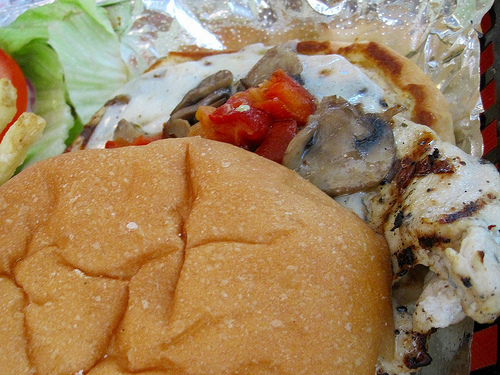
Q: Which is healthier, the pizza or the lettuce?
A: The lettuce is healthier than the pizza.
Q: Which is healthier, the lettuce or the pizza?
A: The lettuce is healthier than the pizza.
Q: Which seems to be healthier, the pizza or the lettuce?
A: The lettuce is healthier than the pizza.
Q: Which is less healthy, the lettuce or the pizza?
A: The pizza is less healthy than the lettuce.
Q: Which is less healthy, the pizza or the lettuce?
A: The pizza is less healthy than the lettuce.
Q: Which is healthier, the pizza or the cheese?
A: The cheese is healthier than the pizza.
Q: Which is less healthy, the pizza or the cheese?
A: The pizza is less healthy than the cheese.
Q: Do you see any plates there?
A: Yes, there is a plate.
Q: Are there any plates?
A: Yes, there is a plate.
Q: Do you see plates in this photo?
A: Yes, there is a plate.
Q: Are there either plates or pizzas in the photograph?
A: Yes, there is a plate.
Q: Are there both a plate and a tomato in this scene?
A: Yes, there are both a plate and a tomato.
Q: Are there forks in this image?
A: No, there are no forks.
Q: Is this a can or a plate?
A: This is a plate.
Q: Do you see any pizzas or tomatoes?
A: Yes, there is a tomato.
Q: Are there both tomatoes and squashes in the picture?
A: No, there is a tomato but no squashes.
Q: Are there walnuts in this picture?
A: No, there are no walnuts.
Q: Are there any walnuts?
A: No, there are no walnuts.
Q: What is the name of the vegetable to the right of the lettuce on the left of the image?
A: The vegetable is a tomato.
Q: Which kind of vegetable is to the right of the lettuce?
A: The vegetable is a tomato.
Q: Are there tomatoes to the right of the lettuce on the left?
A: Yes, there is a tomato to the right of the lettuce.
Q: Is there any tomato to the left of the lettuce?
A: No, the tomato is to the right of the lettuce.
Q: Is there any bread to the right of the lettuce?
A: No, there is a tomato to the right of the lettuce.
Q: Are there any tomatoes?
A: Yes, there is a tomato.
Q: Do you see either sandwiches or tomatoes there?
A: Yes, there is a tomato.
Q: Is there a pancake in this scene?
A: No, there are no pancakes.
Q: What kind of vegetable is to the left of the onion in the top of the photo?
A: The vegetable is a tomato.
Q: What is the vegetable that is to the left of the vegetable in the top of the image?
A: The vegetable is a tomato.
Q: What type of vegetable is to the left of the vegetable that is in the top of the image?
A: The vegetable is a tomato.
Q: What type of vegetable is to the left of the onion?
A: The vegetable is a tomato.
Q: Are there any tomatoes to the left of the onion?
A: Yes, there is a tomato to the left of the onion.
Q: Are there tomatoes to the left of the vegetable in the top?
A: Yes, there is a tomato to the left of the onion.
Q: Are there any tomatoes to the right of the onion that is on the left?
A: No, the tomato is to the left of the onion.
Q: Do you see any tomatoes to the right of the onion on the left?
A: No, the tomato is to the left of the onion.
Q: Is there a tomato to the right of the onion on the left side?
A: No, the tomato is to the left of the onion.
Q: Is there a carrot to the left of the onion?
A: No, there is a tomato to the left of the onion.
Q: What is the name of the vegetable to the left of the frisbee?
A: The vegetable is a tomato.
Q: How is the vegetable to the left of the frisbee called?
A: The vegetable is a tomato.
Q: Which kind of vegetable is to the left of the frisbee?
A: The vegetable is a tomato.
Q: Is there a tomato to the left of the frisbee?
A: Yes, there is a tomato to the left of the frisbee.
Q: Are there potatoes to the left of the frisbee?
A: No, there is a tomato to the left of the frisbee.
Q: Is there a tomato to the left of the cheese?
A: Yes, there is a tomato to the left of the cheese.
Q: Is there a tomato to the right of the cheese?
A: No, the tomato is to the left of the cheese.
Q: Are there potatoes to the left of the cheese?
A: No, there is a tomato to the left of the cheese.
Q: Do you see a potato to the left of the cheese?
A: No, there is a tomato to the left of the cheese.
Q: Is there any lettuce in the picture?
A: Yes, there is lettuce.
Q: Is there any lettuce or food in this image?
A: Yes, there is lettuce.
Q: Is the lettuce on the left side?
A: Yes, the lettuce is on the left of the image.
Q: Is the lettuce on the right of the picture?
A: No, the lettuce is on the left of the image.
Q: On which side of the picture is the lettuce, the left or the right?
A: The lettuce is on the left of the image.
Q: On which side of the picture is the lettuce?
A: The lettuce is on the left of the image.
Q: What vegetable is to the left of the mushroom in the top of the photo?
A: The vegetable is lettuce.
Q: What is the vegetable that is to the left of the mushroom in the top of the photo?
A: The vegetable is lettuce.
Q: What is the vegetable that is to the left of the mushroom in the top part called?
A: The vegetable is lettuce.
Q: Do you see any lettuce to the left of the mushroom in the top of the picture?
A: Yes, there is lettuce to the left of the mushroom.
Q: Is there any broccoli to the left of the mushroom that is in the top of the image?
A: No, there is lettuce to the left of the mushroom.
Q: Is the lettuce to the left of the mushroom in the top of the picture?
A: Yes, the lettuce is to the left of the mushroom.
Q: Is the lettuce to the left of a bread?
A: No, the lettuce is to the left of the mushroom.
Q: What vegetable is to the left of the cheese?
A: The vegetable is lettuce.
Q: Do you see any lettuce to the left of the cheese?
A: Yes, there is lettuce to the left of the cheese.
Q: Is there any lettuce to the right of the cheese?
A: No, the lettuce is to the left of the cheese.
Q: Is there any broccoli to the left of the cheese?
A: No, there is lettuce to the left of the cheese.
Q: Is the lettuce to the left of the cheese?
A: Yes, the lettuce is to the left of the cheese.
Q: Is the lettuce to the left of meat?
A: No, the lettuce is to the left of the cheese.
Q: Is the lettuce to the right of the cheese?
A: No, the lettuce is to the left of the cheese.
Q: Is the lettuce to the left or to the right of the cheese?
A: The lettuce is to the left of the cheese.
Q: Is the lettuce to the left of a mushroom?
A: Yes, the lettuce is to the left of a mushroom.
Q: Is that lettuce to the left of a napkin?
A: No, the lettuce is to the left of a mushroom.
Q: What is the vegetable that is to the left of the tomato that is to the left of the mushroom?
A: The vegetable is lettuce.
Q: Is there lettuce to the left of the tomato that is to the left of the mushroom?
A: Yes, there is lettuce to the left of the tomato.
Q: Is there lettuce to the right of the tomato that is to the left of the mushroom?
A: No, the lettuce is to the left of the tomato.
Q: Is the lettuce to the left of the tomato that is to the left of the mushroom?
A: Yes, the lettuce is to the left of the tomato.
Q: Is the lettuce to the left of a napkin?
A: No, the lettuce is to the left of the tomato.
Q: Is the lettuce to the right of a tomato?
A: No, the lettuce is to the left of a tomato.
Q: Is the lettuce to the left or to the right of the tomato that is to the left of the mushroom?
A: The lettuce is to the left of the tomato.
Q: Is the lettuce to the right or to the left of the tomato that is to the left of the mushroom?
A: The lettuce is to the left of the tomato.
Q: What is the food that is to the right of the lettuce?
A: The food is a mushroom.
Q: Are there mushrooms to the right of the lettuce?
A: Yes, there is a mushroom to the right of the lettuce.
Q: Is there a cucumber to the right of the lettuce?
A: No, there is a mushroom to the right of the lettuce.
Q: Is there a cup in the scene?
A: No, there are no cups.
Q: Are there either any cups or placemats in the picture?
A: No, there are no cups or placemats.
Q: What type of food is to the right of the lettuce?
A: The food is a mushroom.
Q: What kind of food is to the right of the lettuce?
A: The food is a mushroom.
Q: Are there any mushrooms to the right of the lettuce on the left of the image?
A: Yes, there is a mushroom to the right of the lettuce.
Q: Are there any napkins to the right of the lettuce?
A: No, there is a mushroom to the right of the lettuce.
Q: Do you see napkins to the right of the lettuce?
A: No, there is a mushroom to the right of the lettuce.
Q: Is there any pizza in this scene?
A: Yes, there is a pizza.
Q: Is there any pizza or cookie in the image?
A: Yes, there is a pizza.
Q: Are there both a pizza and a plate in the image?
A: Yes, there are both a pizza and a plate.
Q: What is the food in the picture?
A: The food is a pizza.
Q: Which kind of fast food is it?
A: The food is a pizza.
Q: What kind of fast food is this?
A: This is a pizza.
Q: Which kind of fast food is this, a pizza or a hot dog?
A: This is a pizza.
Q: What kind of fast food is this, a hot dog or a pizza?
A: This is a pizza.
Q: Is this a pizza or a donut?
A: This is a pizza.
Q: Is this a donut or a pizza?
A: This is a pizza.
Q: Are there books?
A: No, there are no books.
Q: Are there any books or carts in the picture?
A: No, there are no books or carts.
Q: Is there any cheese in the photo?
A: Yes, there is cheese.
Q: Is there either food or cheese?
A: Yes, there is cheese.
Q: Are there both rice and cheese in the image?
A: No, there is cheese but no rice.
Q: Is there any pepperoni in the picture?
A: No, there is no pepperoni.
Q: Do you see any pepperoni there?
A: No, there is no pepperoni.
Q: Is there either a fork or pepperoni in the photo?
A: No, there are no pepperoni or forks.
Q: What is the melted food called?
A: The food is cheese.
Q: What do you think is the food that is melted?
A: The food is cheese.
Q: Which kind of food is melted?
A: The food is cheese.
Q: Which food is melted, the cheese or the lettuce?
A: The cheese is melted.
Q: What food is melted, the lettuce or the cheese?
A: The cheese is melted.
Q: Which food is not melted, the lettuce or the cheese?
A: The lettuce is not melted.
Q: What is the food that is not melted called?
A: The food is lettuce.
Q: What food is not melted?
A: The food is lettuce.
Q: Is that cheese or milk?
A: That is cheese.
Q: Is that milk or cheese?
A: That is cheese.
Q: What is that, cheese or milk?
A: That is cheese.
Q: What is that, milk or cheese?
A: That is cheese.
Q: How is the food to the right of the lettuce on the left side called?
A: The food is cheese.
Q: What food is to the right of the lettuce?
A: The food is cheese.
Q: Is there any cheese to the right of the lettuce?
A: Yes, there is cheese to the right of the lettuce.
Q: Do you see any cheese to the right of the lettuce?
A: Yes, there is cheese to the right of the lettuce.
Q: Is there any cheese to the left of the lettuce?
A: No, the cheese is to the right of the lettuce.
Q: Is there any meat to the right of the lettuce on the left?
A: No, there is cheese to the right of the lettuce.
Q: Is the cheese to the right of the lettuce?
A: Yes, the cheese is to the right of the lettuce.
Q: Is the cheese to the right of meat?
A: No, the cheese is to the right of the lettuce.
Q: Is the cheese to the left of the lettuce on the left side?
A: No, the cheese is to the right of the lettuce.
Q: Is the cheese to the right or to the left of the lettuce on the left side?
A: The cheese is to the right of the lettuce.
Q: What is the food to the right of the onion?
A: The food is cheese.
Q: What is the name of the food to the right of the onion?
A: The food is cheese.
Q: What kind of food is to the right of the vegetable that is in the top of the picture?
A: The food is cheese.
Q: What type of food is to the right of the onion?
A: The food is cheese.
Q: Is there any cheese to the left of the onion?
A: No, the cheese is to the right of the onion.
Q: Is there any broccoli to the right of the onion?
A: No, there is cheese to the right of the onion.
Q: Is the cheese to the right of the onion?
A: Yes, the cheese is to the right of the onion.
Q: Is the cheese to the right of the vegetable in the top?
A: Yes, the cheese is to the right of the onion.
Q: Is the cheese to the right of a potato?
A: No, the cheese is to the right of the onion.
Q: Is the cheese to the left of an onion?
A: No, the cheese is to the right of an onion.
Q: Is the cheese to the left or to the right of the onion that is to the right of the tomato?
A: The cheese is to the right of the onion.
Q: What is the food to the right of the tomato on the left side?
A: The food is cheese.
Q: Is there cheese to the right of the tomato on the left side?
A: Yes, there is cheese to the right of the tomato.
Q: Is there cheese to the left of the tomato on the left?
A: No, the cheese is to the right of the tomato.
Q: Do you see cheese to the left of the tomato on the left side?
A: No, the cheese is to the right of the tomato.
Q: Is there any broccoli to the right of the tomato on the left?
A: No, there is cheese to the right of the tomato.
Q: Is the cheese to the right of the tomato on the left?
A: Yes, the cheese is to the right of the tomato.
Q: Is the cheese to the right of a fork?
A: No, the cheese is to the right of the tomato.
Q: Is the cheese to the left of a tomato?
A: No, the cheese is to the right of a tomato.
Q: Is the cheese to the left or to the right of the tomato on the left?
A: The cheese is to the right of the tomato.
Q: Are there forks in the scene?
A: No, there are no forks.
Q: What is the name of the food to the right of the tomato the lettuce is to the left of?
A: The food is a mushroom.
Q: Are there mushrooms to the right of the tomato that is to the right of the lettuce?
A: Yes, there is a mushroom to the right of the tomato.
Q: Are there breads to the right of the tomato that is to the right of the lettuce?
A: No, there is a mushroom to the right of the tomato.